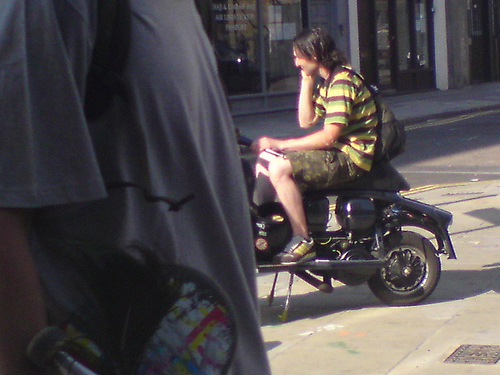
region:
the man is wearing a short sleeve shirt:
[306, 68, 383, 171]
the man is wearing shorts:
[286, 132, 369, 196]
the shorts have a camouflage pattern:
[286, 144, 368, 196]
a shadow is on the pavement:
[252, 255, 494, 327]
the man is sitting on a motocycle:
[253, 31, 456, 304]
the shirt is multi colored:
[314, 66, 384, 168]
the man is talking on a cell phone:
[289, 30, 352, 130]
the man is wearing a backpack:
[364, 83, 411, 166]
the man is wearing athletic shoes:
[271, 233, 319, 269]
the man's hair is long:
[284, 22, 342, 72]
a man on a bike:
[163, 12, 495, 347]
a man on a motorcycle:
[221, 30, 495, 318]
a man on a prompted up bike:
[210, 19, 482, 368]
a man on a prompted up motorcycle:
[184, 13, 461, 365]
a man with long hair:
[225, 25, 450, 238]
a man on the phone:
[218, 8, 418, 260]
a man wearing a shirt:
[235, 12, 476, 280]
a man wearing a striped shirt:
[230, 22, 470, 254]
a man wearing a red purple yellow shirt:
[269, 24, 408, 200]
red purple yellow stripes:
[299, 57, 391, 180]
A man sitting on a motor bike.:
[261, 31, 429, 300]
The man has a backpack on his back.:
[375, 83, 406, 182]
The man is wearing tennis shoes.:
[277, 219, 312, 272]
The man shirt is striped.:
[313, 73, 381, 168]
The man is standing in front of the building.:
[225, 11, 460, 146]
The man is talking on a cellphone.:
[280, 38, 344, 112]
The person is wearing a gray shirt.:
[77, 36, 274, 271]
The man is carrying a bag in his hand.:
[82, 247, 243, 360]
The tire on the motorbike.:
[367, 226, 467, 323]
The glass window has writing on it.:
[211, 6, 258, 46]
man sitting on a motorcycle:
[199, 14, 439, 311]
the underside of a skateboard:
[22, 249, 263, 374]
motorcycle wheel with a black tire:
[364, 224, 443, 308]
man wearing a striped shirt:
[280, 27, 405, 184]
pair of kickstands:
[266, 256, 301, 326]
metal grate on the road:
[444, 333, 499, 369]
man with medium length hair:
[280, 28, 351, 89]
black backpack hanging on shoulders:
[330, 61, 409, 168]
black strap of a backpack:
[76, 0, 138, 139]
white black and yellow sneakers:
[277, 226, 319, 269]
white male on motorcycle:
[242, 25, 406, 270]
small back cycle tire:
[357, 212, 459, 314]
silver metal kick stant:
[255, 257, 312, 330]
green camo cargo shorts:
[275, 129, 377, 203]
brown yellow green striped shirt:
[295, 61, 397, 191]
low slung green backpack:
[357, 67, 412, 173]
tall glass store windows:
[225, 2, 440, 99]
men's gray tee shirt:
[9, 5, 280, 361]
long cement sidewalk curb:
[400, 102, 498, 139]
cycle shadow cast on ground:
[254, 250, 499, 326]